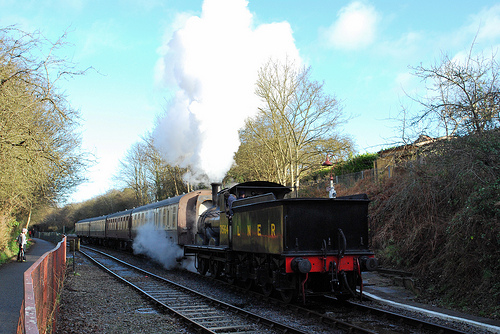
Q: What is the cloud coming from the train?
A: Smoke.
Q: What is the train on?
A: Track.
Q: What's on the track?
A: Train.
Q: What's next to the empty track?
A: Train.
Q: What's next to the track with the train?
A: Empty track.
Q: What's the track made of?
A: Steel.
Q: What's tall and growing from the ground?
A: Trees.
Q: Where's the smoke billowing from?
A: Train.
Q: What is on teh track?
A: Train.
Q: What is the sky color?
A: Blue.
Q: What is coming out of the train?
A: Steam.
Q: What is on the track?
A: Train.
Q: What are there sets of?
A: Tracks.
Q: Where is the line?
A: Ground.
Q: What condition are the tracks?
A: Empty.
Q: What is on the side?
A: Tree.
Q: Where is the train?
A: Track.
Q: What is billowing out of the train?
A: Smoke.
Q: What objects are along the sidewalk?
A: Trees.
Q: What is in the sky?
A: Clouds.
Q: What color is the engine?
A: Black.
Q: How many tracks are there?
A: Two.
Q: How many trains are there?
A: One.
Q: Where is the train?
A: On the tracks.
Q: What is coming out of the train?
A: Steam.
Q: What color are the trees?
A: Green.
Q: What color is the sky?
A: Blue.